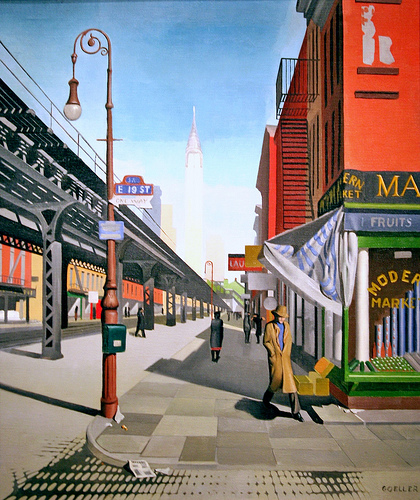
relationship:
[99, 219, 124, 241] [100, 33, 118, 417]
sign on post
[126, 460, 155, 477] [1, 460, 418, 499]
newspaper on street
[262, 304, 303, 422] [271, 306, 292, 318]
man wearing yellow hat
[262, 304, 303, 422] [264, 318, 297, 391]
man wearing yellow coat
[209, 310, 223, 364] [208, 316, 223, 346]
woman wearing a coat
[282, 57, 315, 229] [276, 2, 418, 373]
fire escape on building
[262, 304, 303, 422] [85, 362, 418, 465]
man on sidewalk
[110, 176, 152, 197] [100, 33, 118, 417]
street sign on post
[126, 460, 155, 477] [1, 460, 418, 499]
newspaper in street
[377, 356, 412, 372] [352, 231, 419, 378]
fruit in window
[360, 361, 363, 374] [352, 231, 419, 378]
zuchini in window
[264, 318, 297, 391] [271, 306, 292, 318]
coat matches hat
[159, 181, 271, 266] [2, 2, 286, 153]
clouds in sky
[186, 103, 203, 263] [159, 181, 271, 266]
empire building in clouds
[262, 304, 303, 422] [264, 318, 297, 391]
man wearing a coat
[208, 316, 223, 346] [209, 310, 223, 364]
jacket on woman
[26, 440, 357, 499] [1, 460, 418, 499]
shadow on street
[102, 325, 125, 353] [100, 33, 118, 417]
mailbox on post